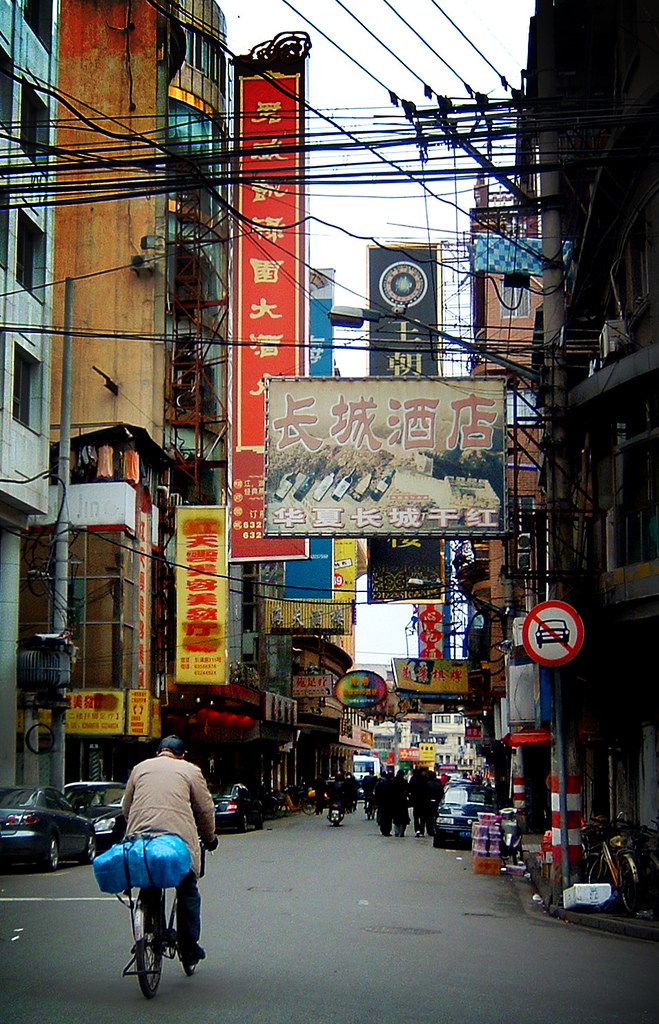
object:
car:
[1, 782, 99, 878]